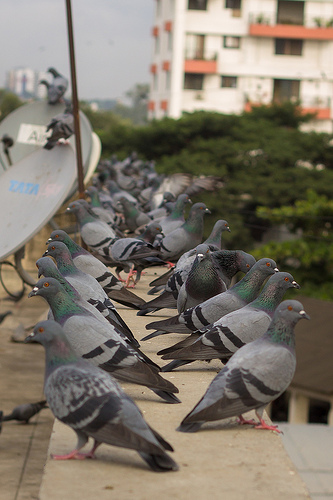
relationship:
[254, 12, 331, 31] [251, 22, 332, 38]
plants on balcony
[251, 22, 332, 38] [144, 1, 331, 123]
balcony on building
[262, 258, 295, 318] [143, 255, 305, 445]
red eyes on three pigeons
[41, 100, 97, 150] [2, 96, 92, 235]
bird on satellite dish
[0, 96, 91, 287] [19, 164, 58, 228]
satellite on satellite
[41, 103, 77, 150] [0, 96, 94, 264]
bird on satellite dish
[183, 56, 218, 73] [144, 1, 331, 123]
balcony on building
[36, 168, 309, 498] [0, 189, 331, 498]
ledge on building